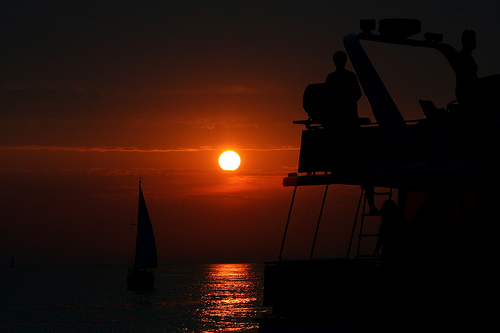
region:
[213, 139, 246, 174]
a bright orange sun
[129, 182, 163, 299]
a sail boat on the water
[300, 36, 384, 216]
a man on a boat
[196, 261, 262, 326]
reflection in the water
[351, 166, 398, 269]
a ladder on a boat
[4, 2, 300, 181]
clouds around the sun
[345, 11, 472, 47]
lights on a boat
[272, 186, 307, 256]
cables on a boat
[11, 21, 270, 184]
a orange sun set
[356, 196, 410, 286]
a person by a ladder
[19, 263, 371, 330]
the beautiful seawater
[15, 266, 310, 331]
the water looks calm and soothing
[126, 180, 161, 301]
a boat in the water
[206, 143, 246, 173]
the sun is an orange color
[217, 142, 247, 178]
the sun is about to go down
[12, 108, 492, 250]
the sky is a brown and orange color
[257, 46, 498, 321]
a huge boat in the water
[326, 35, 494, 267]
people are on the boat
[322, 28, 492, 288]
the amount of people is four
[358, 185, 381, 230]
someone is climbing up a ladder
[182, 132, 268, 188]
glowing white circle in red sky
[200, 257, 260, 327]
red and yellow reflections on water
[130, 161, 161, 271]
dark triangular curve of sail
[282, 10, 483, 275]
silhouette of person on open structure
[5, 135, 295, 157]
wavy white line across sky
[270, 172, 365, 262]
slanted supports under platform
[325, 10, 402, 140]
slanted beam behind person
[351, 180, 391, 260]
leg on rungs of ladder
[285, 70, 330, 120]
curved surface on panel in front of person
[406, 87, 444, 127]
lid open at a slant over flat panel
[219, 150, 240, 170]
Sun in the middle of sky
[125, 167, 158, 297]
A small sail boat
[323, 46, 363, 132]
A silhouetteof a man.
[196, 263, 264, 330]
Reflecion of sun shining on water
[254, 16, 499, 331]
The back end of a boat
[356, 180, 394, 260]
ladder on a boat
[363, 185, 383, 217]
Silhouette of a man's leg.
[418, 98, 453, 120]
Silhouette of a chair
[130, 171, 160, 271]
A sail on a sailboat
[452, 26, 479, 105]
A person standing on a boat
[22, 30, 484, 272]
a sunset over a lake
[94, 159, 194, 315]
a sailboat on the lake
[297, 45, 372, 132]
a shadowy figure on a boat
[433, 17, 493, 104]
this is another person on a boat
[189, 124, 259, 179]
the sun looks spooky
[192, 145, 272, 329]
the sun's reflection on the water looks ominous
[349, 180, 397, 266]
a ladder on a boat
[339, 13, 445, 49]
lights on a boat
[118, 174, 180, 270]
the sail on a boat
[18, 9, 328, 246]
the night time sky over the water